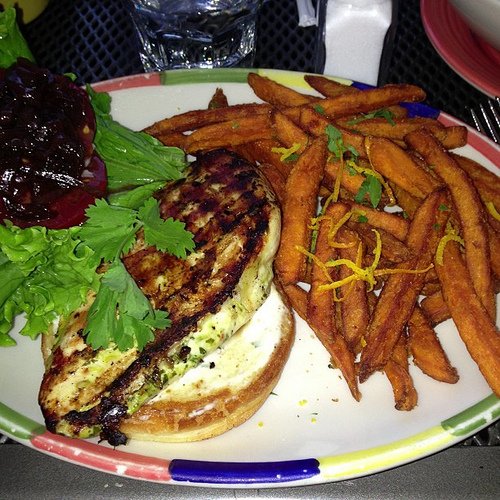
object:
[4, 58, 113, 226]
tomato garnish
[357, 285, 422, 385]
chip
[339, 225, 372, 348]
chips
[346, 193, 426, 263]
fries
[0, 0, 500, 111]
table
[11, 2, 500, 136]
rubber mat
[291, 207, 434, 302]
salmon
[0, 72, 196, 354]
arugula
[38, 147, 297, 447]
bread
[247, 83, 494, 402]
fries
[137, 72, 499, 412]
fries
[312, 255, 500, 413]
fries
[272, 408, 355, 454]
plate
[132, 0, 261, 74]
glass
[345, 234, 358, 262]
part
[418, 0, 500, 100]
edge